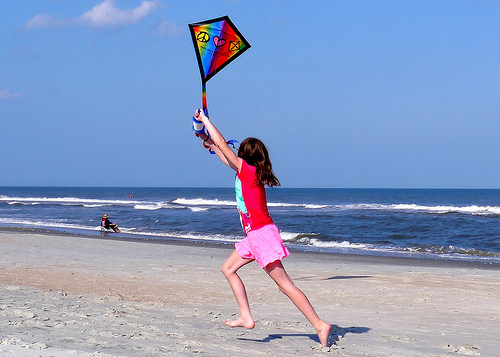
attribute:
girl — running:
[193, 108, 338, 347]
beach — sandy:
[1, 230, 499, 355]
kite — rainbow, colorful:
[187, 16, 253, 115]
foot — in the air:
[223, 313, 258, 331]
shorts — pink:
[233, 225, 292, 270]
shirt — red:
[234, 156, 275, 234]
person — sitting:
[101, 213, 121, 234]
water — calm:
[1, 186, 499, 259]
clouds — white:
[21, 2, 190, 44]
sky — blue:
[1, 1, 499, 187]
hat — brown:
[103, 213, 111, 219]